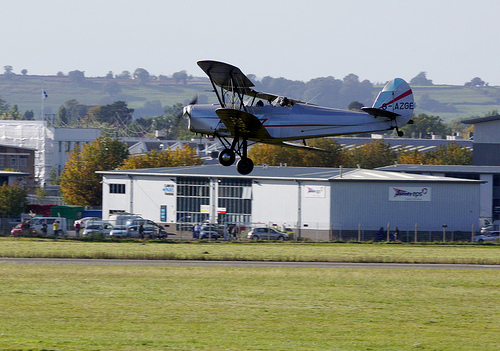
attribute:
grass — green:
[31, 276, 218, 346]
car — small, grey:
[246, 223, 289, 242]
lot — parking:
[2, 210, 324, 250]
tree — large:
[57, 131, 134, 218]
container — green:
[37, 199, 85, 231]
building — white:
[88, 153, 475, 233]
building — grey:
[114, 150, 489, 235]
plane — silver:
[159, 46, 459, 196]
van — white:
[20, 204, 70, 236]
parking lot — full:
[15, 221, 235, 253]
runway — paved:
[21, 243, 475, 289]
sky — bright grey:
[67, 3, 457, 76]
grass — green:
[88, 275, 389, 344]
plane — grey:
[177, 40, 458, 218]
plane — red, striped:
[175, 60, 400, 191]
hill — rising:
[34, 55, 443, 134]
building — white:
[94, 153, 499, 280]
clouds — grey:
[75, 3, 431, 98]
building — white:
[2, 107, 180, 209]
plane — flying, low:
[172, 40, 442, 179]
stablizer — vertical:
[366, 73, 436, 130]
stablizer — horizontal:
[353, 101, 403, 124]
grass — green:
[35, 237, 443, 261]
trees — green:
[64, 152, 131, 217]